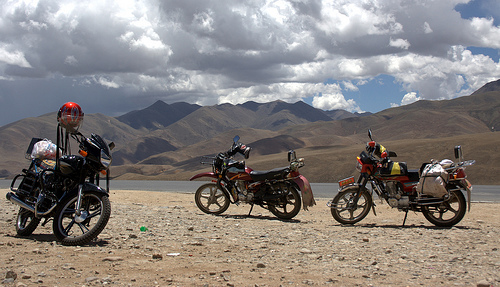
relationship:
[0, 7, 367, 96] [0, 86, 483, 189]
clouds over a mountain top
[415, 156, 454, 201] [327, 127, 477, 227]
bag strapped to back of bike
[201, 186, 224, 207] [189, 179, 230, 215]
spokes inside a tire wheel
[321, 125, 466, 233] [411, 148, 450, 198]
bike with bag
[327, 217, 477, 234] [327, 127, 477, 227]
shadow from bike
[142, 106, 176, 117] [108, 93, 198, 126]
darkness cast on mountain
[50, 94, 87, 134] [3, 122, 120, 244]
helmet on bike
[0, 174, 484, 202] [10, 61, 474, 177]
river in mountainous area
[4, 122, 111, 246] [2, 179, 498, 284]
bike on shore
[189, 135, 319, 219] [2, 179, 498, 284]
motorcycle on shore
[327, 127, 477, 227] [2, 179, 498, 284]
bike on shore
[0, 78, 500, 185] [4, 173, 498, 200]
mountain on other side of water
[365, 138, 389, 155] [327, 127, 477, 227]
accents on bike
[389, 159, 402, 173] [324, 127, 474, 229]
paint covering bike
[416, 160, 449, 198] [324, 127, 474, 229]
bag hanging from bike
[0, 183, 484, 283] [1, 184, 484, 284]
dirt covering ground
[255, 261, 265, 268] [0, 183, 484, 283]
rock lying in dirt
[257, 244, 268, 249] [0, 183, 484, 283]
rock lying in dirt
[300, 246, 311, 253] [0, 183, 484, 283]
rock lying in dirt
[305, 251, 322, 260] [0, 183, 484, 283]
rock lying in dirt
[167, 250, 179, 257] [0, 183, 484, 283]
rock lying in dirt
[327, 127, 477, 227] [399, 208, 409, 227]
bike leaning on kickstand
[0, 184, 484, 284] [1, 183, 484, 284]
gravel covering road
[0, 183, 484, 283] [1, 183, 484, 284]
dirt covering road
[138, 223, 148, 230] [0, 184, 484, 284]
bottle lying in gravel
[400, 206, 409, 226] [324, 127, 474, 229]
kickstand holding up bike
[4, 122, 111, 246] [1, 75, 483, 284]
bike parked in area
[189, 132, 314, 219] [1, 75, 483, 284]
motorcycle parked in area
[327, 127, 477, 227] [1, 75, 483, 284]
bike parked in area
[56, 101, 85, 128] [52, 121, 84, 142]
helmet placed on handlebar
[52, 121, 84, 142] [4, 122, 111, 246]
handlebar attached to bike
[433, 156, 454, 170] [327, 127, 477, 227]
storage pack hanging from bike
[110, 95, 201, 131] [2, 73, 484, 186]
area belonging to mountain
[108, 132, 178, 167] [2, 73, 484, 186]
area belonging to mountain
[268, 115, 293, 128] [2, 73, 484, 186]
area belonging to mountain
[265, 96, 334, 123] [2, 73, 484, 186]
area belonging to mountain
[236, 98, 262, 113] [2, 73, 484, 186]
area belonging to mountain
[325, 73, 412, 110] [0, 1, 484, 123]
patch appearing in sky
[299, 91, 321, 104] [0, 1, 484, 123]
patch appearing in sky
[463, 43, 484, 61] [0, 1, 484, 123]
patch appearing in sky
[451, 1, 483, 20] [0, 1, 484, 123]
patch appearing in sky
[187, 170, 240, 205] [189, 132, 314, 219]
front fender mounted on motorcycle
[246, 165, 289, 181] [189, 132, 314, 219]
seat mounted on motorcycle